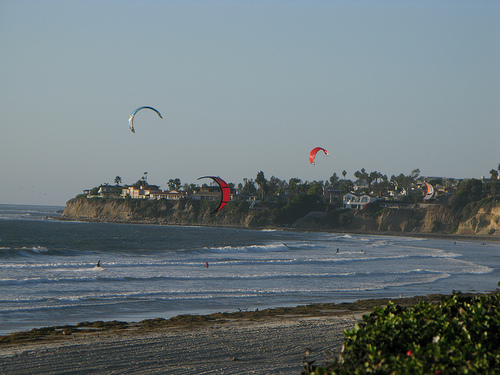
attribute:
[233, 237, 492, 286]
waves — crashing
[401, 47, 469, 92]
clouds — White 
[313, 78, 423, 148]
clouds — white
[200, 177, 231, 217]
kite — red, black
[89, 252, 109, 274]
person — standing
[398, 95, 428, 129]
clouds — white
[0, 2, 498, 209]
sky — blue, clear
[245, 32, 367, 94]
sky — blue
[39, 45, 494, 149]
sky — blue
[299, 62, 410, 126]
clouds sky — blue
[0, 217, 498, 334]
water — surface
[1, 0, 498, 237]
sky — Blue 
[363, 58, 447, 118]
clouds — white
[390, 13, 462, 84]
clouds — white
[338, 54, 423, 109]
clouds — white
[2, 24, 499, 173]
sky — blue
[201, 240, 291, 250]
sea foam — white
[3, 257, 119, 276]
sea foam — white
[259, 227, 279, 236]
sea foam — white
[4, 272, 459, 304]
sea foam — white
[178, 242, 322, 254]
wave — surface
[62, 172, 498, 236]
hill — seaside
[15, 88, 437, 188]
clouds — white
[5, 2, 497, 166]
sky — blue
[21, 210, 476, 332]
ripples — small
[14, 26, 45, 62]
cloud — white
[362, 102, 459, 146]
cloud — white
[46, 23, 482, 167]
sky — blue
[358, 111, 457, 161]
cloud — white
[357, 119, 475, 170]
cloud — white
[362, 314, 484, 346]
leaves — green